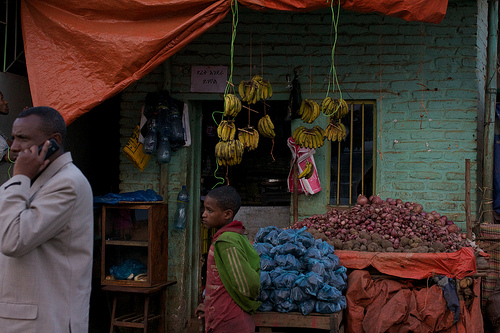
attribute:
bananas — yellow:
[213, 76, 345, 167]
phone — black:
[31, 138, 61, 162]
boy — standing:
[198, 183, 266, 333]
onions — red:
[281, 194, 469, 256]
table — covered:
[333, 246, 478, 282]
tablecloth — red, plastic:
[333, 247, 475, 281]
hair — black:
[207, 184, 245, 217]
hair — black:
[16, 103, 69, 143]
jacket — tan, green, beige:
[1, 153, 96, 332]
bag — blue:
[107, 257, 148, 280]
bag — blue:
[257, 224, 275, 240]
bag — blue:
[310, 238, 332, 260]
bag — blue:
[303, 274, 334, 294]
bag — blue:
[257, 252, 281, 273]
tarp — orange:
[19, 2, 233, 128]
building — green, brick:
[112, 2, 488, 332]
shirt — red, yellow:
[202, 222, 254, 327]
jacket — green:
[213, 229, 265, 314]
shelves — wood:
[96, 195, 166, 290]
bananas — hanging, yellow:
[209, 75, 354, 170]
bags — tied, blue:
[250, 224, 351, 314]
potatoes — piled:
[308, 230, 466, 258]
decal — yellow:
[206, 249, 225, 299]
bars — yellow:
[327, 99, 372, 207]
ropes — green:
[224, 1, 239, 93]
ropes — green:
[321, 1, 355, 110]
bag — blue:
[96, 189, 163, 206]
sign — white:
[189, 64, 230, 95]